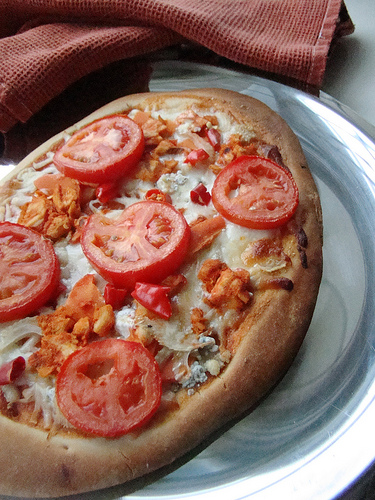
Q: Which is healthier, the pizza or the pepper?
A: The pepper is healthier than the pizza.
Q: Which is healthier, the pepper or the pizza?
A: The pepper is healthier than the pizza.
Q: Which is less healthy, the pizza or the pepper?
A: The pizza is less healthy than the pepper.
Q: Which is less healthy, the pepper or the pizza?
A: The pizza is less healthy than the pepper.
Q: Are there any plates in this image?
A: Yes, there is a plate.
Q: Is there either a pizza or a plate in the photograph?
A: Yes, there is a plate.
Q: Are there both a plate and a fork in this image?
A: No, there is a plate but no forks.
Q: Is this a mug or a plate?
A: This is a plate.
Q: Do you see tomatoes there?
A: Yes, there is a tomato.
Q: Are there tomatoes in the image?
A: Yes, there is a tomato.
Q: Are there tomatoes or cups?
A: Yes, there is a tomato.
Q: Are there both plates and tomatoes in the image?
A: Yes, there are both a tomato and a plate.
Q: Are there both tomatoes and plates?
A: Yes, there are both a tomato and a plate.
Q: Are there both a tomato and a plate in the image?
A: Yes, there are both a tomato and a plate.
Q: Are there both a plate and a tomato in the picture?
A: Yes, there are both a tomato and a plate.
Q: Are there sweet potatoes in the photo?
A: No, there are no sweet potatoes.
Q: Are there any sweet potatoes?
A: No, there are no sweet potatoes.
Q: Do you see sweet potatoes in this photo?
A: No, there are no sweet potatoes.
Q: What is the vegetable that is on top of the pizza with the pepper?
A: The vegetable is a tomato.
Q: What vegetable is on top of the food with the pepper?
A: The vegetable is a tomato.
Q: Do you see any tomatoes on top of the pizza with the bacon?
A: Yes, there is a tomato on top of the pizza.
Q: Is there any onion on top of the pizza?
A: No, there is a tomato on top of the pizza.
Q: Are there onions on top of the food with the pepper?
A: No, there is a tomato on top of the pizza.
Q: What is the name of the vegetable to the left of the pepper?
A: The vegetable is a tomato.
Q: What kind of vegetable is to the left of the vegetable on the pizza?
A: The vegetable is a tomato.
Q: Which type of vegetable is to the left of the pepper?
A: The vegetable is a tomato.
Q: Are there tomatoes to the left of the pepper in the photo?
A: Yes, there is a tomato to the left of the pepper.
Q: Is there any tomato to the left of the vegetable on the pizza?
A: Yes, there is a tomato to the left of the pepper.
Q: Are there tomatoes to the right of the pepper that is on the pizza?
A: No, the tomato is to the left of the pepper.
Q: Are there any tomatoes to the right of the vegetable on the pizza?
A: No, the tomato is to the left of the pepper.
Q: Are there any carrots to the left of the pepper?
A: No, there is a tomato to the left of the pepper.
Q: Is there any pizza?
A: Yes, there is a pizza.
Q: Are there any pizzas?
A: Yes, there is a pizza.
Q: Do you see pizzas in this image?
A: Yes, there is a pizza.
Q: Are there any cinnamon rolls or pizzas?
A: Yes, there is a pizza.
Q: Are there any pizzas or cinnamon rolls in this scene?
A: Yes, there is a pizza.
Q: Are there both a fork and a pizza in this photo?
A: No, there is a pizza but no forks.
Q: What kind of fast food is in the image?
A: The fast food is a pizza.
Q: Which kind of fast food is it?
A: The food is a pizza.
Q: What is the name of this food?
A: This is a pizza.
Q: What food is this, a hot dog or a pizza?
A: This is a pizza.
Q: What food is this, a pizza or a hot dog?
A: This is a pizza.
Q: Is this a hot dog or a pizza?
A: This is a pizza.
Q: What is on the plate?
A: The pizza is on the plate.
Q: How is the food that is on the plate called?
A: The food is a pizza.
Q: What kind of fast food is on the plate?
A: The food is a pizza.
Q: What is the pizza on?
A: The pizza is on the plate.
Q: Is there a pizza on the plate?
A: Yes, there is a pizza on the plate.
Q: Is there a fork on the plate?
A: No, there is a pizza on the plate.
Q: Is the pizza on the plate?
A: Yes, the pizza is on the plate.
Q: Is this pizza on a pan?
A: No, the pizza is on the plate.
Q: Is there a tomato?
A: Yes, there is a tomato.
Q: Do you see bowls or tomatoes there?
A: Yes, there is a tomato.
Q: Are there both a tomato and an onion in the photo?
A: No, there is a tomato but no onions.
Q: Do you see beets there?
A: No, there are no beets.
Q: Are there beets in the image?
A: No, there are no beets.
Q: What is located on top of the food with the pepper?
A: The tomato is on top of the pizza.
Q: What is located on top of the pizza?
A: The tomato is on top of the pizza.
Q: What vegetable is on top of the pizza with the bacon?
A: The vegetable is a tomato.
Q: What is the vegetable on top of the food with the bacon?
A: The vegetable is a tomato.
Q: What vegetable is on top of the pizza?
A: The vegetable is a tomato.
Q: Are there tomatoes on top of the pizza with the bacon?
A: Yes, there is a tomato on top of the pizza.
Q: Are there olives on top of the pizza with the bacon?
A: No, there is a tomato on top of the pizza.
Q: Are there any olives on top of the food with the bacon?
A: No, there is a tomato on top of the pizza.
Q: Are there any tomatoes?
A: Yes, there is a tomato.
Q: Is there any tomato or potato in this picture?
A: Yes, there is a tomato.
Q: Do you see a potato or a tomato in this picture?
A: Yes, there is a tomato.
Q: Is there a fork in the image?
A: No, there are no forks.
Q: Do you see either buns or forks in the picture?
A: No, there are no forks or buns.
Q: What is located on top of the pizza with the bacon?
A: The tomato is on top of the pizza.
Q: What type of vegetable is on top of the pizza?
A: The vegetable is a tomato.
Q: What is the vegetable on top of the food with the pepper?
A: The vegetable is a tomato.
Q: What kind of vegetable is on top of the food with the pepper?
A: The vegetable is a tomato.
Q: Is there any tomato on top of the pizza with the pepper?
A: Yes, there is a tomato on top of the pizza.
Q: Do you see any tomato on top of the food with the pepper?
A: Yes, there is a tomato on top of the pizza.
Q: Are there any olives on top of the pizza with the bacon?
A: No, there is a tomato on top of the pizza.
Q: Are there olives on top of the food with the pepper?
A: No, there is a tomato on top of the pizza.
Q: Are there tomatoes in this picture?
A: Yes, there is a tomato.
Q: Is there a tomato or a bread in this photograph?
A: Yes, there is a tomato.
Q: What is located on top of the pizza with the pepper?
A: The tomato is on top of the pizza.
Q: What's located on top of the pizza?
A: The tomato is on top of the pizza.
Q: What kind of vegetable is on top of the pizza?
A: The vegetable is a tomato.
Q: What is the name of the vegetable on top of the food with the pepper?
A: The vegetable is a tomato.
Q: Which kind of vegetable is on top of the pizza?
A: The vegetable is a tomato.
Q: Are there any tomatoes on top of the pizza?
A: Yes, there is a tomato on top of the pizza.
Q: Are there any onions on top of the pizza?
A: No, there is a tomato on top of the pizza.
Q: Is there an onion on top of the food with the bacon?
A: No, there is a tomato on top of the pizza.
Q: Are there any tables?
A: Yes, there is a table.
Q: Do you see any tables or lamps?
A: Yes, there is a table.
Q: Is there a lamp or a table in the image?
A: Yes, there is a table.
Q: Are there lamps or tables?
A: Yes, there is a table.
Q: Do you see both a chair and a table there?
A: No, there is a table but no chairs.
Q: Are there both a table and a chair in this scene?
A: No, there is a table but no chairs.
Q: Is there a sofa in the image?
A: No, there are no sofas.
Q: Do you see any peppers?
A: Yes, there is a pepper.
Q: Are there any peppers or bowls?
A: Yes, there is a pepper.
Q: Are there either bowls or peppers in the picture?
A: Yes, there is a pepper.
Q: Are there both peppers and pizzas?
A: Yes, there are both a pepper and a pizza.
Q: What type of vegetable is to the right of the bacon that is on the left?
A: The vegetable is a pepper.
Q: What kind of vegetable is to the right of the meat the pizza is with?
A: The vegetable is a pepper.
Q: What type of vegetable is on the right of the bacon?
A: The vegetable is a pepper.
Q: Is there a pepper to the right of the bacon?
A: Yes, there is a pepper to the right of the bacon.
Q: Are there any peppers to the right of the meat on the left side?
A: Yes, there is a pepper to the right of the bacon.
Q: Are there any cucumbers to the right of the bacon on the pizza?
A: No, there is a pepper to the right of the bacon.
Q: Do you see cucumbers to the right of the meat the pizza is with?
A: No, there is a pepper to the right of the bacon.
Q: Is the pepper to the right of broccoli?
A: No, the pepper is to the right of the bacon.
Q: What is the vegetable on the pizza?
A: The vegetable is a pepper.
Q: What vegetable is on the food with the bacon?
A: The vegetable is a pepper.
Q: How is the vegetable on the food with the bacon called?
A: The vegetable is a pepper.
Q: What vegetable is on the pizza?
A: The vegetable is a pepper.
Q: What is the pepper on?
A: The pepper is on the pizza.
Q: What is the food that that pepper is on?
A: The food is a pizza.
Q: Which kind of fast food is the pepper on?
A: The pepper is on the pizza.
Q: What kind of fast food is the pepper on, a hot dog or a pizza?
A: The pepper is on a pizza.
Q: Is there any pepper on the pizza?
A: Yes, there is a pepper on the pizza.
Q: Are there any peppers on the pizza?
A: Yes, there is a pepper on the pizza.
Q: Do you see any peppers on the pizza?
A: Yes, there is a pepper on the pizza.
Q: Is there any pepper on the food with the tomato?
A: Yes, there is a pepper on the pizza.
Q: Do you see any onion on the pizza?
A: No, there is a pepper on the pizza.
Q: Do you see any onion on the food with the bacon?
A: No, there is a pepper on the pizza.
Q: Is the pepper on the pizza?
A: Yes, the pepper is on the pizza.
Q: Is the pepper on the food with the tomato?
A: Yes, the pepper is on the pizza.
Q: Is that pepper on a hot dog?
A: No, the pepper is on the pizza.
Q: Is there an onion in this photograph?
A: No, there are no onions.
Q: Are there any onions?
A: No, there are no onions.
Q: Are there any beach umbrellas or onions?
A: No, there are no onions or beach umbrellas.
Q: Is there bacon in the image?
A: Yes, there is bacon.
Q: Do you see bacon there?
A: Yes, there is bacon.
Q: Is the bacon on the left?
A: Yes, the bacon is on the left of the image.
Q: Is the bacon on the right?
A: No, the bacon is on the left of the image.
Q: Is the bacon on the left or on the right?
A: The bacon is on the left of the image.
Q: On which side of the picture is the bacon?
A: The bacon is on the left of the image.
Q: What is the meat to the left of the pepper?
A: The meat is bacon.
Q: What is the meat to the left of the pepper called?
A: The meat is bacon.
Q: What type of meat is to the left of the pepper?
A: The meat is bacon.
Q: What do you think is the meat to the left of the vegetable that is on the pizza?
A: The meat is bacon.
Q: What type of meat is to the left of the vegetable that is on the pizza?
A: The meat is bacon.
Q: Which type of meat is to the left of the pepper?
A: The meat is bacon.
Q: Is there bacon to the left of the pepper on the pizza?
A: Yes, there is bacon to the left of the pepper.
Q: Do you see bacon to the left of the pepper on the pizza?
A: Yes, there is bacon to the left of the pepper.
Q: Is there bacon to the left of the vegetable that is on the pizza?
A: Yes, there is bacon to the left of the pepper.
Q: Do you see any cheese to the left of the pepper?
A: No, there is bacon to the left of the pepper.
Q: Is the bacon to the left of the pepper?
A: Yes, the bacon is to the left of the pepper.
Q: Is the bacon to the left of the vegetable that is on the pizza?
A: Yes, the bacon is to the left of the pepper.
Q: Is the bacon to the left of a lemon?
A: No, the bacon is to the left of the pepper.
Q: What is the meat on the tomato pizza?
A: The meat is bacon.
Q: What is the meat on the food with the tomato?
A: The meat is bacon.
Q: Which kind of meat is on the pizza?
A: The meat is bacon.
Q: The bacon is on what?
A: The bacon is on the pizza.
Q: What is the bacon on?
A: The bacon is on the pizza.